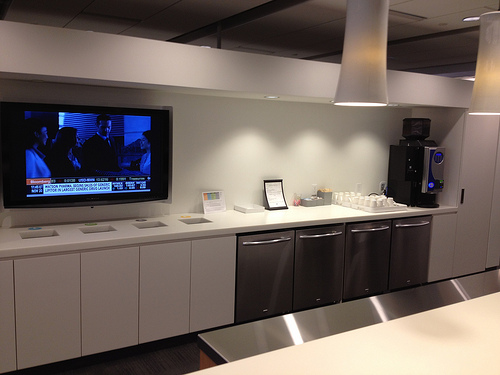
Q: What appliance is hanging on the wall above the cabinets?
A: A television.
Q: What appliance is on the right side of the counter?
A: A coffee maker.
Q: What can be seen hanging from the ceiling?
A: Light fixtures.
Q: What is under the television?
A: White cabinets.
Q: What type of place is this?
A: Kitchen.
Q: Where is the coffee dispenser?
A: Next to the television.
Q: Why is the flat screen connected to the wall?
A: To provide entertainment to those in the kitchen.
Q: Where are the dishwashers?
A: Next to the white cabinets.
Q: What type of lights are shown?
A: Fluorescent lights hanging from the ceiling.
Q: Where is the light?
A: Beneath the ceiling.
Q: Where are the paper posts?
A: Hanging on the wall.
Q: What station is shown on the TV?
A: News.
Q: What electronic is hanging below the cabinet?
A: A television.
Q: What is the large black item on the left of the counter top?
A: A coffee maker.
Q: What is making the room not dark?
A: Lights.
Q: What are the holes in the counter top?
A: Trash bins.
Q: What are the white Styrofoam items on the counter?
A: Cups.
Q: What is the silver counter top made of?
A: Metal.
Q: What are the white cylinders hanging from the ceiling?
A: Lights.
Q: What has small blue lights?
A: Coffee maker.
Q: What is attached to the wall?
A: A television.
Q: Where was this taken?
A: In an office break room.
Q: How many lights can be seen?
A: Two.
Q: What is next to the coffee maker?
A: Cups.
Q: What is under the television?
A: Holes for throwing items into recycling bins.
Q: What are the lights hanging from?
A: The ceiling.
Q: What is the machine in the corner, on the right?
A: A coffee maker.